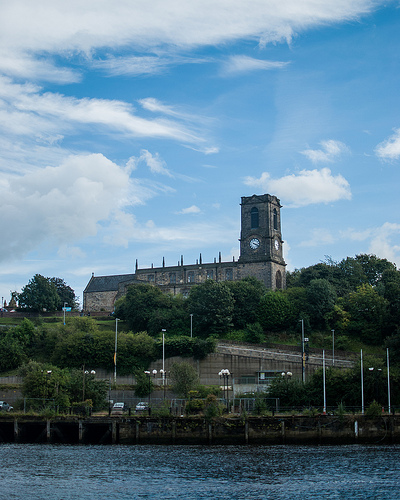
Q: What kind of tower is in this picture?
A: A clock tower.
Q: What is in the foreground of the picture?
A: Water.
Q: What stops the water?
A: Canal walls.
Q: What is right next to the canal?
A: A parking lot.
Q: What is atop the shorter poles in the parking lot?
A: Lights.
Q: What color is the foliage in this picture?
A: Green.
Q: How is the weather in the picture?
A: Partly cloudy.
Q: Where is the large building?
A: On top of a hill.